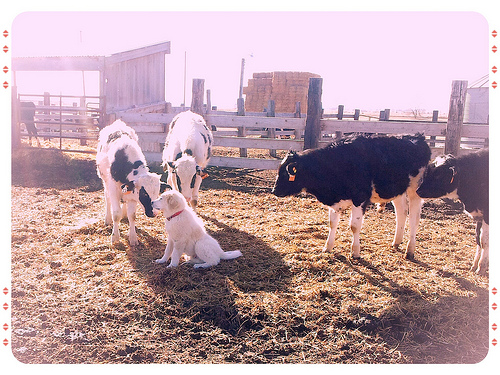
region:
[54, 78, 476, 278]
many animals in the photo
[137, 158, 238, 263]
dog on the ground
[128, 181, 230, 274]
dog sitting down on ground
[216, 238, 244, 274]
tail of the dog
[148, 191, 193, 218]
head of the dog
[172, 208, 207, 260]
white fur on the dog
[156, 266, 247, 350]
shadow on the ground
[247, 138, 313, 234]
head of a cow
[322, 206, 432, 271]
legs of the cow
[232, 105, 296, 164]
fence behind the animals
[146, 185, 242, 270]
white dog sitting amongst 4 cows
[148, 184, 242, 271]
white dog with red collar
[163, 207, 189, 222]
red collar on white dog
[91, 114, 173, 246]
black and white cow closest to the dog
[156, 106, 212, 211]
black and white cow checking out the dog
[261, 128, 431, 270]
black cow with white legs approaching dog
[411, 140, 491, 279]
black and white cow entering the picture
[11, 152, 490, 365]
pen that the dog and cows are in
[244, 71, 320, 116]
baled hay on a wagon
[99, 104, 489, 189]
fence keeping the cattle in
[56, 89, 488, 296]
four cows and a dog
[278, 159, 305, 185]
tag on cow's ear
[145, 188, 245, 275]
yellow Retriever sitting on some straw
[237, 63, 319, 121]
large stack of straw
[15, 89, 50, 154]
back end of a horse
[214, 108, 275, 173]
part of wood fencing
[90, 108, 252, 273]
two white cows and a dog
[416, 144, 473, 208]
head of a brown cow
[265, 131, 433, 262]
black cow with white belly and legs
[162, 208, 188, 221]
red collar on dog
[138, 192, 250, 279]
a dog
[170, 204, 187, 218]
red collar on the dog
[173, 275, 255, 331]
the shadow on the dirt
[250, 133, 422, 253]
a cow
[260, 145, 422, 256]
the cow is standing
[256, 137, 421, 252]
the cow is black and white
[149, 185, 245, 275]
a white dog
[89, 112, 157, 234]
the cow is white and black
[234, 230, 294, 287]
a shadow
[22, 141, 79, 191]
a shadow on the ground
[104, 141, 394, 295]
These are many animals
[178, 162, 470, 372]
This is a pasture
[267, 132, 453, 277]
this is a cow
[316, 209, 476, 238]
These are four legs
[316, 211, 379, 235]
This is a knee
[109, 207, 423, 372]
This is a dog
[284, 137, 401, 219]
The cow is black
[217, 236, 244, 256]
This is a tail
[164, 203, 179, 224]
This is a collar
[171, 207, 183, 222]
The collar is red